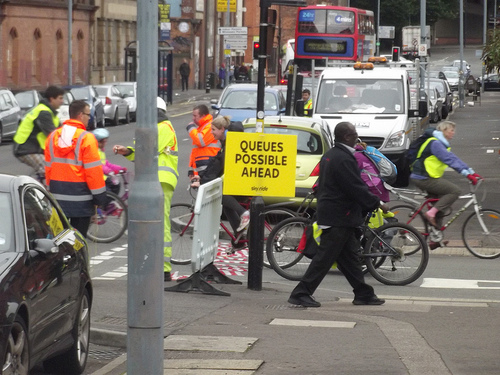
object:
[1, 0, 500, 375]
city street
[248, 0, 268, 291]
black pole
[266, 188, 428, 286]
bike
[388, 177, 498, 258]
bike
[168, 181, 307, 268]
bike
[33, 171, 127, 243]
bike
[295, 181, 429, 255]
bike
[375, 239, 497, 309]
crosswalk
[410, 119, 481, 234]
man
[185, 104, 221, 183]
man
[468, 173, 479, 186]
gloves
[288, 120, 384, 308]
man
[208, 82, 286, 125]
vehicle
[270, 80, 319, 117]
vehicle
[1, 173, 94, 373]
black car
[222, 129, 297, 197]
sign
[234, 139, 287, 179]
words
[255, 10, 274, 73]
pole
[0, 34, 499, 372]
street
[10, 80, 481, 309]
foreground people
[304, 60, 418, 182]
truck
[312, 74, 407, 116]
windshield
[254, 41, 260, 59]
light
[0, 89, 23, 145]
car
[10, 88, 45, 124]
car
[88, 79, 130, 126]
car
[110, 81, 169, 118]
car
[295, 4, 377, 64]
bus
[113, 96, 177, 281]
man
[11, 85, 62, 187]
man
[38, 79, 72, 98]
hat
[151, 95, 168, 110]
hat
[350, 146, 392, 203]
people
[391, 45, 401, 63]
light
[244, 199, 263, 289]
pole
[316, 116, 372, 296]
side view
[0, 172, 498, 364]
foreground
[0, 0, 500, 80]
background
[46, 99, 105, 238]
man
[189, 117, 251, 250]
person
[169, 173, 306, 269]
bike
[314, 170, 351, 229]
black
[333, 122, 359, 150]
head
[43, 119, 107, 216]
coat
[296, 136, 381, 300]
suit